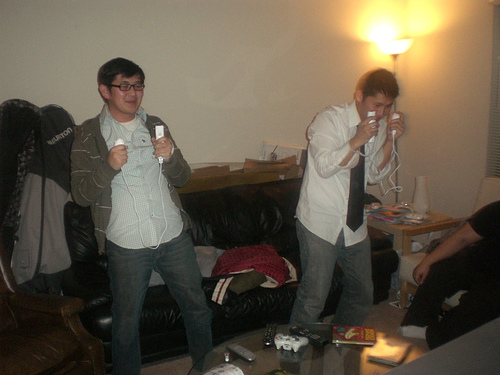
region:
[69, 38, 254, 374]
Man holding two controllers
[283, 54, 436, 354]
Man in white shirt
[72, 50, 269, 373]
Man having fun playing a game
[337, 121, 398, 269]
black tie on white shirt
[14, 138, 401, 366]
Messy black sofa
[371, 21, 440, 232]
Skinny black and white lamp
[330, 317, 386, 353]
Small red and yellow book on table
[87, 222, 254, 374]
Blue jeans on a man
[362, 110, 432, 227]
Two white controllers in mans hands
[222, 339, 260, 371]
Black and silver remote controller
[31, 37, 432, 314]
two young Asian men playing a video game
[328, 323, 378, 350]
red book on the coffee table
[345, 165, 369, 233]
black tie worn by the young man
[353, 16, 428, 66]
bright lamp shining in the corner of the room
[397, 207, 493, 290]
arm of a person sitting in a chair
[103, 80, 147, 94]
black eyeglasses worn by a young man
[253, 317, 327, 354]
two black TV remotes and a white video game controller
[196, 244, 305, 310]
articles of clothing laying on the sofa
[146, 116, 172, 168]
white video game controller in the young man's hand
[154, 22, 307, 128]
white un-decorated wall of the room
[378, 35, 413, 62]
the top of the lamp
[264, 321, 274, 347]
a remote on the table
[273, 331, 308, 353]
a white game controller on the table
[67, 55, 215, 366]
a man in a brown jacket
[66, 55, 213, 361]
a man wearing glasses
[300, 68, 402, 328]
a man wearing a white shirt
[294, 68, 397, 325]
a man wearing a black tie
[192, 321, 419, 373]
a glass table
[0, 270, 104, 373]
a brown chair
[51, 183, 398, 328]
a black couch behind the men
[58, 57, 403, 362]
men playing electronic game in cluttered room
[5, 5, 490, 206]
white walls with yellow light from standing lamp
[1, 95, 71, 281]
pile of fabric behind player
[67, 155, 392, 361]
dark sofa with clothing on seat and papers behind back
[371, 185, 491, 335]
seated man in front of end table with covered surface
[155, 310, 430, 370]
coffee table with cellphone and books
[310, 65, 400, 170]
man with bent elbows holding remote controls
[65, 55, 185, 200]
man holding controls at chest height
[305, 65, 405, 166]
man hiding behind remote controls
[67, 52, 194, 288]
man leaning backwards and laughing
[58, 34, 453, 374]
they are playing a video game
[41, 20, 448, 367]
they are both holding Nintendo Will controllers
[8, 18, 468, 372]
they are both Asian men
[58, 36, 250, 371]
he is wearing glasses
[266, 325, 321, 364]
a white XBOX 360 controller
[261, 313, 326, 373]
the XBOX controller is wireless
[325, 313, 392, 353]
a red book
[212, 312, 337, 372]
various television remote controls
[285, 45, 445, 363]
he is wearing a black tie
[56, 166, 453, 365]
they are standing in front of a black leather couch